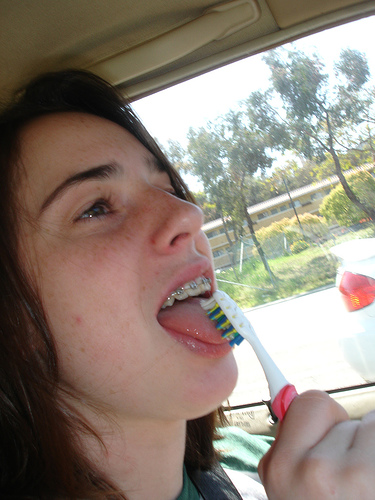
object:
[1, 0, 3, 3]
zebra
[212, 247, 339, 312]
grass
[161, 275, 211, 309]
teeth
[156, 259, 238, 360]
mouth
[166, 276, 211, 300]
braces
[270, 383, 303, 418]
grip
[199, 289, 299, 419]
toothbrush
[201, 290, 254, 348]
head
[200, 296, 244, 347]
bristles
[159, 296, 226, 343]
tongue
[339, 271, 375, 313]
tail light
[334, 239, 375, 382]
car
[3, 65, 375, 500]
girl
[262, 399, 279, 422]
lock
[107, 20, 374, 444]
car door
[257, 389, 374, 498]
hand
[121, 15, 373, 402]
window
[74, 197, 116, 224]
eyes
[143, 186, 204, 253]
nose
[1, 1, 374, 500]
car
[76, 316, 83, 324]
pimple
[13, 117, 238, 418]
face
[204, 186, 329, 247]
windows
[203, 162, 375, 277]
building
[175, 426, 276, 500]
shirt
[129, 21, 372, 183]
sky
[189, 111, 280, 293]
tree